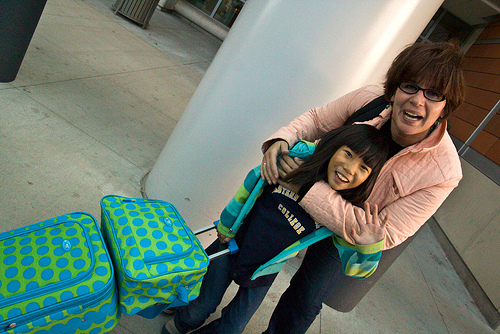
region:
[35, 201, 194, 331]
blue and green suitcases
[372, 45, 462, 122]
woman wearing glasses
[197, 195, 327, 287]
girlwearing a college shirt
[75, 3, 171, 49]
brown trash can on ground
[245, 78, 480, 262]
a woman and a girl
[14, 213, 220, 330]
two polka dot luggage pieces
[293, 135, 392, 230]
a girl smiling at camera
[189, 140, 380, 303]
blue an green sweater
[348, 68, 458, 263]
woman in a pink jacket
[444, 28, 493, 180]
brown shade on window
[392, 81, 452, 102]
eye glasses on woman's face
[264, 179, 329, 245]
college logo on girl's sweat shirt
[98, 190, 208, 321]
blue and green polka dot overnight bag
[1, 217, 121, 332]
blue and green polka dot rolling suitcase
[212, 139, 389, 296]
multi-shade green striped hoodie jacket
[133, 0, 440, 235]
large white support beam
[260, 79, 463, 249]
peach-colored quilted jacket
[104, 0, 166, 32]
round, gated trash bin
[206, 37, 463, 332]
woman and child smiling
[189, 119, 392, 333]
young female child waving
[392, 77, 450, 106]
black glasses on a woman's face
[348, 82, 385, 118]
the black strap of a bag on the woman's shoulder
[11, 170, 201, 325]
blue and green polka dot luggage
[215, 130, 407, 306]
a little girl in a striped jacket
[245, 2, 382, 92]
a wide white post behind two people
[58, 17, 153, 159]
concrete tiles on the ground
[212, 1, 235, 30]
windows of a building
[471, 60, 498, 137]
brown bricks on the side of a building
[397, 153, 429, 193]
quilted peach colored fabric on a coat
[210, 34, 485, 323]
a woman and child smiling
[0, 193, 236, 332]
A piece of luggage.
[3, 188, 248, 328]
The luggage is blue and green.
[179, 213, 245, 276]
The luggage has a handle.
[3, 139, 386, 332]
The luggage matches the person's top.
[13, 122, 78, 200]
The ground is white.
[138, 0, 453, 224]
A white pillar.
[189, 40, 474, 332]
Two people are in the picture.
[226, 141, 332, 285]
The person is wearing a blue shirt.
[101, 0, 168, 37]
A trash can.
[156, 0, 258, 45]
A window is in the background.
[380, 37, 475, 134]
short brown hair hair on a woman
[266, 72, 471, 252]
a pink jacket on a woman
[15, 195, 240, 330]
two blue and green suitcases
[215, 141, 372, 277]
a blue and green sweater on a girl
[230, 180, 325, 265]
a navy shirt on a girl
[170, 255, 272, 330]
blue jeans on a girl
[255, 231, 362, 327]
jeans on a woman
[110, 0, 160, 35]
a trash can in the background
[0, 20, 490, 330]
a concrete floor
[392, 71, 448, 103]
glasses on a woman's face